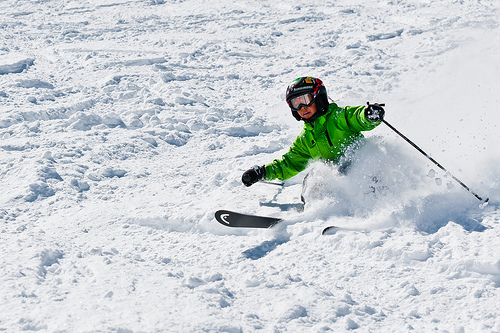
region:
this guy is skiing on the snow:
[40, 22, 467, 330]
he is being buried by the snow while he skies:
[194, 72, 487, 257]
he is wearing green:
[209, 82, 399, 187]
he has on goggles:
[280, 73, 343, 129]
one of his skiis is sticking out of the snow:
[182, 199, 307, 247]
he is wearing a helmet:
[269, 74, 336, 119]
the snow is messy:
[22, 19, 239, 164]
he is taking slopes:
[152, 74, 484, 266]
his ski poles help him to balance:
[244, 125, 499, 230]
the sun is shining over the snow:
[42, 29, 456, 272]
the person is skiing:
[135, 42, 415, 252]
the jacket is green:
[244, 95, 354, 206]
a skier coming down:
[193, 54, 458, 266]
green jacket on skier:
[210, 85, 392, 205]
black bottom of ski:
[207, 198, 298, 254]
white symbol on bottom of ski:
[213, 208, 235, 228]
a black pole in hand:
[368, 98, 499, 235]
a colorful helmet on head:
[282, 72, 334, 122]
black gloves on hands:
[239, 158, 278, 208]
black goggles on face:
[283, 87, 318, 114]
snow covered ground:
[11, 2, 498, 319]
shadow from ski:
[242, 229, 313, 273]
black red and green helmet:
[286, 76, 329, 120]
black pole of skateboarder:
[362, 102, 498, 213]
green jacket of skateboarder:
[266, 103, 381, 178]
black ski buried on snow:
[211, 206, 282, 231]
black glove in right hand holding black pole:
[365, 103, 385, 122]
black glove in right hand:
[244, 162, 267, 182]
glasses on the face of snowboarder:
[289, 89, 320, 107]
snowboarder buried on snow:
[219, 78, 397, 233]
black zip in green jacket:
[321, 128, 333, 148]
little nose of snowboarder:
[299, 105, 307, 116]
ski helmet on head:
[283, 75, 327, 112]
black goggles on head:
[288, 93, 313, 109]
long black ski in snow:
[213, 209, 290, 232]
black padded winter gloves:
[240, 164, 265, 185]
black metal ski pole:
[371, 106, 496, 213]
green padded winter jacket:
[258, 105, 381, 177]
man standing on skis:
[214, 76, 391, 241]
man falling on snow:
[212, 77, 390, 245]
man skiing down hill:
[216, 74, 480, 243]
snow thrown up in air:
[387, 48, 499, 218]